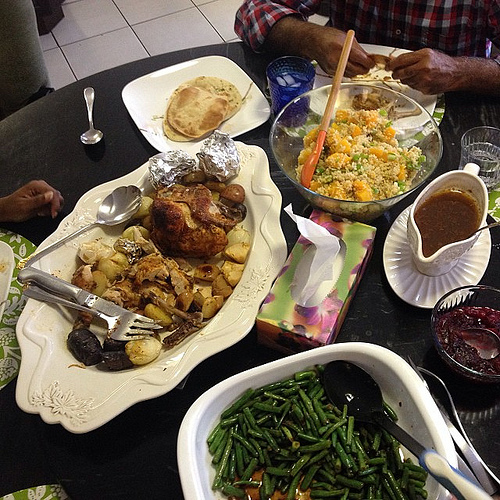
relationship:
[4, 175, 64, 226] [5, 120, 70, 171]
hand on table top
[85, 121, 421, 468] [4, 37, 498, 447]
meal on table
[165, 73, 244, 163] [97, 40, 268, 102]
patty on plate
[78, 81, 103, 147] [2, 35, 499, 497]
spoon on table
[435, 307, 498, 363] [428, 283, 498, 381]
grape in cup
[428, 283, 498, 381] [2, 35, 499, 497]
cup on table